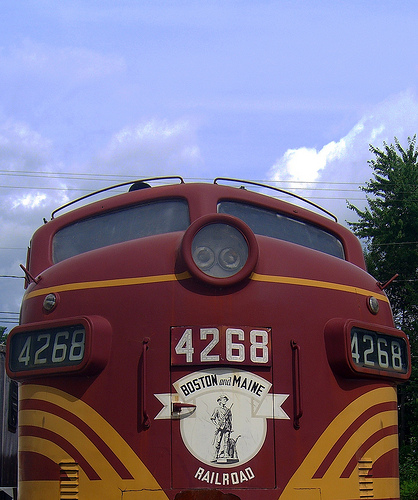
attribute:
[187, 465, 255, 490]
word — white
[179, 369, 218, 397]
word — black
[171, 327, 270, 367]
numbers — white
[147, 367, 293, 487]
logo — black, white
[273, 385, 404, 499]
design — yellow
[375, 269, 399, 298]
handle — burgundy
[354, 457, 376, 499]
vents — yellow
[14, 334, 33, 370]
number 4 — white, written in white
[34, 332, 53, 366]
number 2 — written in white, white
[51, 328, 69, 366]
number 6 — white, written in white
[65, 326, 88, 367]
number 8 — written in white